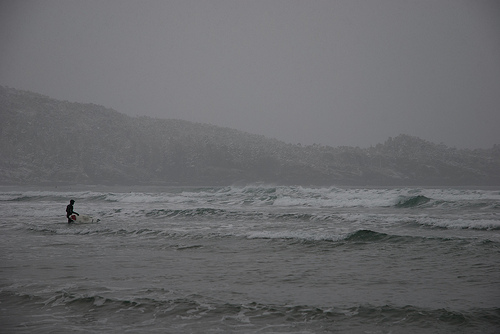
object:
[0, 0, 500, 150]
sky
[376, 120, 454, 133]
dusk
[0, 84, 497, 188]
mountains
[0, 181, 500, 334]
water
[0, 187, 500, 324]
waves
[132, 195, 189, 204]
foam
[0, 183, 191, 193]
shore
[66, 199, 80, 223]
person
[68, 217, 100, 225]
surfboard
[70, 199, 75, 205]
head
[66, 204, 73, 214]
torso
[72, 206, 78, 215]
arm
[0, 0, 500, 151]
clouds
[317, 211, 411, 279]
sea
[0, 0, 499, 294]
foggy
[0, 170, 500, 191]
coast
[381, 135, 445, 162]
trees